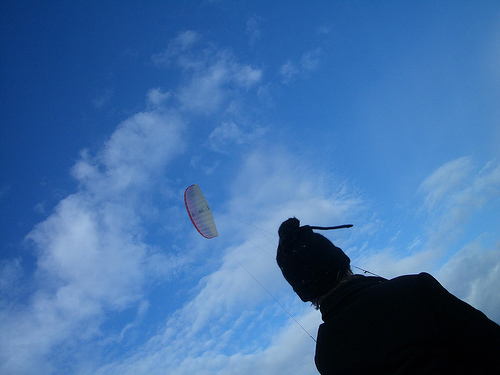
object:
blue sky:
[59, 7, 447, 177]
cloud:
[256, 80, 286, 110]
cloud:
[148, 27, 200, 69]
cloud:
[276, 47, 322, 88]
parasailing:
[184, 182, 219, 240]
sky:
[0, 5, 500, 374]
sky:
[6, 8, 106, 137]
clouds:
[32, 168, 172, 371]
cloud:
[110, 127, 161, 194]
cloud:
[59, 185, 119, 238]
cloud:
[416, 164, 451, 235]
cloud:
[141, 301, 216, 347]